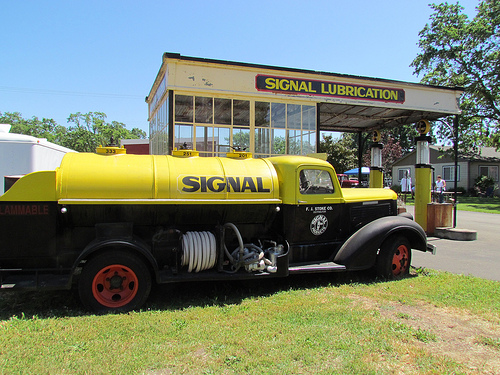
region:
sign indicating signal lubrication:
[252, 67, 411, 109]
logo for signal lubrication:
[173, 169, 274, 198]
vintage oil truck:
[11, 131, 434, 311]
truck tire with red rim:
[73, 244, 158, 326]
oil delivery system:
[164, 209, 289, 291]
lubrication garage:
[105, 24, 479, 257]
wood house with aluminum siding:
[386, 131, 494, 218]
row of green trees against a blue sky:
[0, 67, 435, 191]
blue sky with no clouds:
[20, 1, 491, 181]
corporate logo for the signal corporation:
[288, 198, 351, 260]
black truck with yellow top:
[7, 120, 455, 320]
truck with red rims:
[10, 135, 442, 327]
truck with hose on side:
[10, 133, 440, 310]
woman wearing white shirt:
[435, 168, 450, 217]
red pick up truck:
[332, 165, 361, 193]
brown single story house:
[388, 128, 498, 212]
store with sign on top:
[140, 42, 462, 210]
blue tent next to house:
[345, 159, 377, 184]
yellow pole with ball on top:
[407, 118, 434, 252]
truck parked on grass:
[5, 145, 412, 372]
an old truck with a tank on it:
[0, 148, 433, 316]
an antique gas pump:
[414, 135, 432, 232]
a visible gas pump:
[369, 140, 382, 187]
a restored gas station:
[144, 52, 473, 238]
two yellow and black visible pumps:
[366, 132, 433, 230]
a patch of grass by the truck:
[4, 271, 497, 373]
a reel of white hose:
[182, 230, 220, 272]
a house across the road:
[390, 143, 497, 193]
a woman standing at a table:
[434, 171, 449, 199]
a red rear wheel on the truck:
[94, 265, 137, 307]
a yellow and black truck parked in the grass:
[0, 139, 438, 314]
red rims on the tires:
[88, 243, 411, 310]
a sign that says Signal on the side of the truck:
[178, 171, 269, 195]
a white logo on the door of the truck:
[303, 202, 335, 237]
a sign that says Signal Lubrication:
[258, 70, 405, 103]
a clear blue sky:
[0, 0, 498, 142]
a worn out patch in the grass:
[347, 287, 499, 374]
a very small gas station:
[128, 43, 479, 245]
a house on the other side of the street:
[389, 138, 499, 198]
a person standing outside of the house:
[433, 175, 447, 195]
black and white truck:
[25, 119, 415, 288]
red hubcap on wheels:
[89, 261, 141, 303]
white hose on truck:
[178, 218, 257, 288]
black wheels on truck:
[73, 256, 170, 318]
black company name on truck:
[147, 175, 309, 205]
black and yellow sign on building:
[171, 51, 460, 129]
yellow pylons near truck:
[358, 150, 440, 244]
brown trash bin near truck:
[414, 182, 462, 237]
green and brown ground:
[72, 269, 417, 374]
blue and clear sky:
[28, 8, 152, 133]